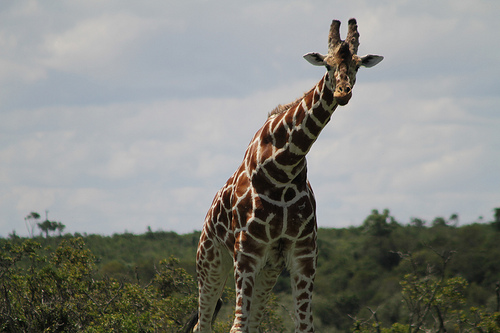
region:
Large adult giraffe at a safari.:
[9, 4, 484, 323]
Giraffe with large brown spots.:
[184, 16, 399, 317]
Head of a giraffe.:
[301, 14, 391, 116]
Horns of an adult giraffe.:
[290, 7, 388, 123]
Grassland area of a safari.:
[7, 209, 495, 329]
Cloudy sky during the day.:
[18, 11, 498, 258]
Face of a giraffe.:
[320, 57, 366, 108]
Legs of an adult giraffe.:
[181, 217, 349, 328]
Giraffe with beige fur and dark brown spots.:
[160, 13, 392, 330]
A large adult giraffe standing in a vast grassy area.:
[1, 9, 495, 331]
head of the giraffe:
[303, 17, 382, 106]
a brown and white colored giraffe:
[189, 15, 385, 332]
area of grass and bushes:
[0, 207, 499, 332]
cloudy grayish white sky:
[0, 0, 499, 240]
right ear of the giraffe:
[301, 52, 327, 67]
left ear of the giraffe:
[361, 52, 383, 69]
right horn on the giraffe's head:
[325, 18, 345, 48]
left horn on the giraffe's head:
[341, 16, 358, 46]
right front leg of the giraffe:
[228, 238, 269, 332]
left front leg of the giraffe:
[282, 243, 321, 332]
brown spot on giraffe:
[294, 101, 307, 128]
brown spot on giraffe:
[284, 97, 300, 132]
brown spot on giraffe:
[302, 113, 320, 137]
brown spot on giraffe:
[287, 125, 313, 153]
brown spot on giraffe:
[271, 120, 289, 151]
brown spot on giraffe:
[258, 117, 275, 163]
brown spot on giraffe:
[235, 171, 248, 199]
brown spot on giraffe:
[250, 169, 275, 194]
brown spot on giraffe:
[282, 186, 297, 203]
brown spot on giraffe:
[244, 219, 272, 245]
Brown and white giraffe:
[185, 17, 384, 331]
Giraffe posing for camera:
[191, 15, 383, 329]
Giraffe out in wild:
[17, 13, 492, 329]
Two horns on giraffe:
[322, 15, 361, 45]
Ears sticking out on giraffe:
[303, 45, 383, 70]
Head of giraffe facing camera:
[301, 17, 383, 106]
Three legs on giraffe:
[194, 224, 318, 331]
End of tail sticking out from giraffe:
[177, 278, 227, 331]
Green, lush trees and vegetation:
[1, 212, 498, 331]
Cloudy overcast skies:
[3, 5, 498, 222]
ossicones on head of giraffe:
[322, 12, 363, 44]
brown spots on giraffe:
[255, 185, 306, 236]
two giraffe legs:
[228, 251, 320, 328]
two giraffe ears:
[297, 45, 387, 71]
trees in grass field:
[16, 200, 66, 238]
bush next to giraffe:
[1, 230, 192, 330]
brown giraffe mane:
[257, 80, 317, 120]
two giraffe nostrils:
[333, 80, 353, 93]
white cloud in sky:
[17, 17, 167, 105]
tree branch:
[365, 306, 387, 331]